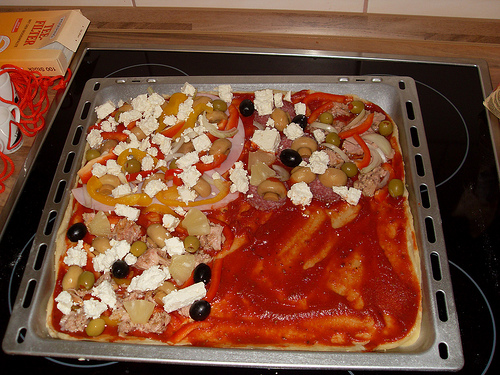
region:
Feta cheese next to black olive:
[163, 275, 207, 317]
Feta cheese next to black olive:
[249, 125, 283, 155]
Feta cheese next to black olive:
[60, 241, 89, 262]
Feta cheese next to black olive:
[309, 149, 336, 179]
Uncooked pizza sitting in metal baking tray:
[52, 75, 423, 352]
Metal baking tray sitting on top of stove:
[0, 73, 462, 368]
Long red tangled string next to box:
[0, 65, 70, 195]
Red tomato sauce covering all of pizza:
[48, 92, 423, 346]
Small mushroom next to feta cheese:
[254, 180, 287, 202]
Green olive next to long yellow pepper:
[122, 156, 140, 174]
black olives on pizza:
[185, 250, 232, 350]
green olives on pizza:
[123, 220, 243, 260]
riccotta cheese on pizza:
[88, 237, 228, 308]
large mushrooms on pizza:
[206, 175, 348, 216]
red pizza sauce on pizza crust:
[231, 220, 438, 370]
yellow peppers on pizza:
[89, 183, 230, 212]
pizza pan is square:
[45, 213, 481, 369]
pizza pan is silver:
[13, 225, 339, 358]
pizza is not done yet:
[212, 225, 432, 346]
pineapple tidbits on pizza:
[101, 290, 187, 336]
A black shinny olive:
[187, 300, 212, 321]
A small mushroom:
[256, 177, 291, 203]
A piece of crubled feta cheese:
[223, 160, 249, 196]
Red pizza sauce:
[363, 256, 414, 318]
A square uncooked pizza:
[46, 81, 433, 351]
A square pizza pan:
[4, 71, 468, 373]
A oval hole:
[433, 285, 450, 328]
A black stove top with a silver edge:
[3, 28, 498, 373]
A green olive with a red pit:
[343, 97, 370, 113]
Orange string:
[0, 66, 75, 139]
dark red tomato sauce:
[242, 214, 416, 342]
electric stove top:
[432, 60, 478, 371]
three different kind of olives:
[63, 215, 198, 330]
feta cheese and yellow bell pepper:
[90, 88, 239, 206]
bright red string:
[13, 74, 62, 124]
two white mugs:
[2, 80, 29, 140]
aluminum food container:
[40, 80, 465, 360]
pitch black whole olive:
[275, 143, 310, 173]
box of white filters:
[1, 10, 78, 72]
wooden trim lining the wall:
[93, 10, 497, 58]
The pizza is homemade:
[59, 69, 356, 360]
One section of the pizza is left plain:
[213, 182, 455, 369]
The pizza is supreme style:
[215, 90, 400, 207]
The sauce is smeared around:
[243, 213, 407, 358]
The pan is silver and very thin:
[379, 70, 461, 355]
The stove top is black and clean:
[419, 127, 471, 337]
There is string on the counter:
[0, 50, 54, 148]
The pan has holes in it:
[402, 82, 443, 256]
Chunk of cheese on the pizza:
[155, 256, 200, 321]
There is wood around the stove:
[182, 10, 389, 75]